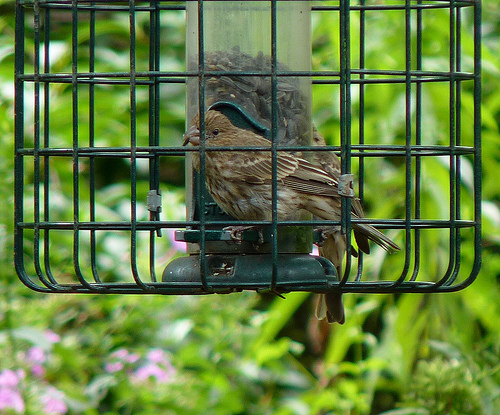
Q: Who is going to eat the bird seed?
A: Birds.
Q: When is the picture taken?
A: Daytime.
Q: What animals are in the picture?
A: Birds.